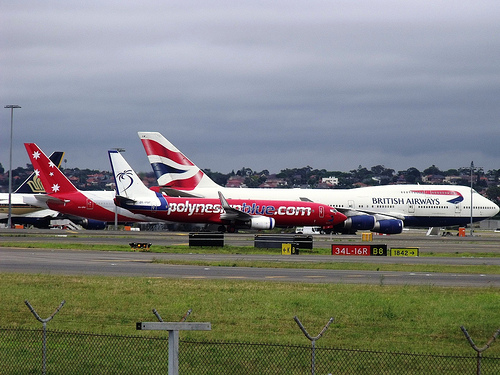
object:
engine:
[249, 214, 275, 229]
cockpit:
[450, 185, 499, 218]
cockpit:
[325, 206, 340, 213]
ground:
[358, 148, 435, 182]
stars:
[31, 150, 42, 160]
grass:
[0, 272, 497, 373]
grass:
[153, 253, 500, 274]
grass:
[0, 237, 500, 262]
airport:
[0, 0, 500, 375]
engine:
[343, 213, 404, 234]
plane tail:
[103, 147, 152, 205]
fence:
[0, 298, 498, 373]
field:
[0, 271, 500, 375]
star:
[51, 183, 60, 193]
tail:
[20, 138, 77, 193]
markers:
[329, 241, 419, 259]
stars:
[49, 171, 55, 177]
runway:
[0, 245, 500, 264]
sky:
[0, 0, 500, 178]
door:
[318, 206, 324, 218]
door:
[454, 201, 460, 213]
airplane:
[0, 151, 67, 221]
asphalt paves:
[0, 254, 498, 286]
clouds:
[0, 0, 500, 169]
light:
[3, 102, 22, 110]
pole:
[6, 107, 14, 229]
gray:
[146, 57, 232, 94]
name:
[371, 196, 442, 206]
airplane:
[108, 150, 346, 233]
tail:
[137, 129, 223, 191]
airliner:
[20, 132, 499, 238]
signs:
[389, 245, 420, 258]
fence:
[129, 235, 500, 258]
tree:
[116, 167, 134, 197]